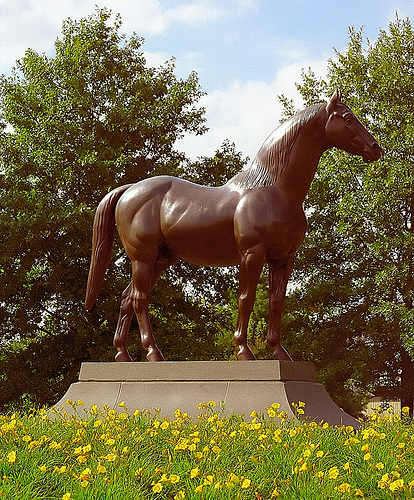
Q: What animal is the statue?
A: Horse.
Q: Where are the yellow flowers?
A: Around the statue.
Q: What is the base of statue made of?
A: Cement.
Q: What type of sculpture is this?
A: Horse statue.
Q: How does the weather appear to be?
A: Sunny.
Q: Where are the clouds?
A: In sky.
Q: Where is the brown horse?
A: On cement base.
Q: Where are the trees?
A: Behind horse.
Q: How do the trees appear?
A: Full of leaves.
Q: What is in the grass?
A: Yellow flowers.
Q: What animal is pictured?
A: Horse.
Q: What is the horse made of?
A: Stone.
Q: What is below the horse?
A: Flowers.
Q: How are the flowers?
A: Yellow.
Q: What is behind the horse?
A: Trees.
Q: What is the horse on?
A: Slab.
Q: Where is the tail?
A: On the horse.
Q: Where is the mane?
A: On the horse.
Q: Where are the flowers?
A: On the ground.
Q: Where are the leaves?
A: On the tree.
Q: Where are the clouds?
A: In the sky.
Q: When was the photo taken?
A: Daytime.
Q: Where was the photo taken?
A: By the horse statue.